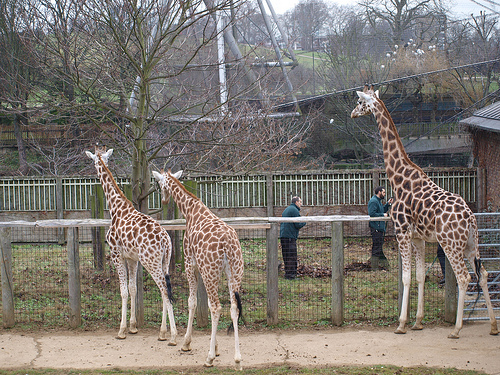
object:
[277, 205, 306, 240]
jacket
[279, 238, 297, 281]
pants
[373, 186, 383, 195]
hair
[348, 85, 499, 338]
giraffe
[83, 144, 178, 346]
giraffe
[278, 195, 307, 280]
person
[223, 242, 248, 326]
tail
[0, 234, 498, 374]
ground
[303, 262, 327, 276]
leaves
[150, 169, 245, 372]
giraffe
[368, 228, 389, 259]
pants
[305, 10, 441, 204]
tree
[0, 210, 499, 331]
fence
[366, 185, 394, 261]
men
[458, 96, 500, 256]
building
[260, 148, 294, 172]
leaves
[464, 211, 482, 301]
tail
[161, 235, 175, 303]
tail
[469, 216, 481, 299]
black tail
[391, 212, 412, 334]
front leg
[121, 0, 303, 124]
tower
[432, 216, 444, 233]
pattern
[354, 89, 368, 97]
ears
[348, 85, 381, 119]
head